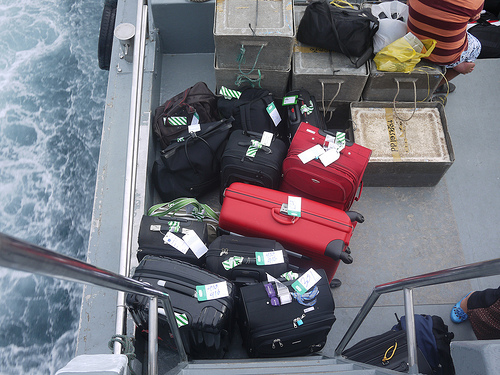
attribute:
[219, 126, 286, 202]
luggage — black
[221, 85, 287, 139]
luggage — black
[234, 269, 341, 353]
luggage — black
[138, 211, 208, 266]
luggage — black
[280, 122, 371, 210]
luggage — red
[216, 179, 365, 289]
luggage — red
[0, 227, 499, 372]
stairs — silver, gray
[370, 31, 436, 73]
sheer bag — yellow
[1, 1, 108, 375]
water — white, rough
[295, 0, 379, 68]
bag — black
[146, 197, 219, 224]
rope handle — green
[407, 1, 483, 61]
shirt — striped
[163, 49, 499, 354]
part of floor — gray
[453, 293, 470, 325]
shoe — blue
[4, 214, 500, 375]
railing — metal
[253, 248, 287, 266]
luggage tag — blue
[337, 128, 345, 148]
tag — striped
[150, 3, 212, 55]
container — gray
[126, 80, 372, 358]
suit cases — lined up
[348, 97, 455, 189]
box — square shaped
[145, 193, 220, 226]
bag — green